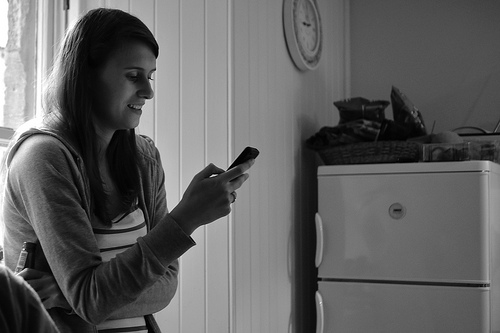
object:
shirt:
[88, 206, 149, 333]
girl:
[2, 8, 255, 333]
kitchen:
[0, 0, 500, 333]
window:
[0, 0, 69, 138]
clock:
[282, 0, 323, 73]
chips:
[306, 85, 428, 151]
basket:
[317, 140, 423, 166]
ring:
[231, 193, 236, 203]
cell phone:
[226, 147, 259, 182]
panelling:
[87, 0, 351, 333]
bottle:
[13, 242, 38, 275]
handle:
[315, 212, 324, 267]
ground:
[208, 59, 241, 81]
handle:
[315, 290, 323, 332]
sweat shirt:
[1, 110, 198, 333]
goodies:
[339, 104, 404, 169]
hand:
[181, 158, 255, 225]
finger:
[217, 159, 256, 182]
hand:
[17, 268, 71, 310]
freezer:
[313, 160, 499, 333]